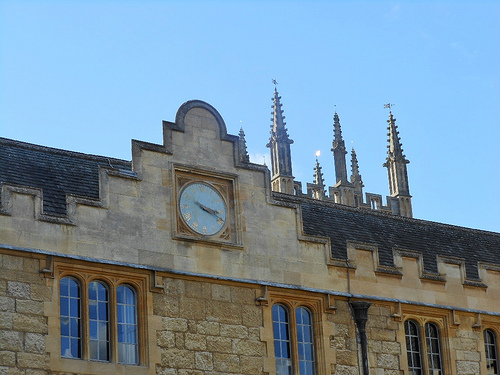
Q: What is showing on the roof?
A: A clock.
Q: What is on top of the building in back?
A: Five spires.